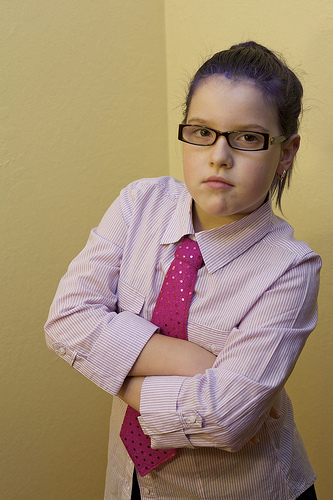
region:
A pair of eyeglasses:
[173, 118, 289, 157]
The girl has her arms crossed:
[37, 35, 323, 460]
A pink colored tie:
[117, 236, 207, 479]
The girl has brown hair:
[173, 36, 305, 221]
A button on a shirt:
[139, 481, 153, 498]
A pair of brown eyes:
[189, 123, 259, 148]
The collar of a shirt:
[156, 186, 277, 278]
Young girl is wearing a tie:
[42, 38, 325, 481]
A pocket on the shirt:
[112, 277, 149, 318]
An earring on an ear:
[275, 163, 290, 184]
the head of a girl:
[148, 62, 313, 269]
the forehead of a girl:
[194, 66, 291, 137]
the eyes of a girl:
[171, 120, 291, 158]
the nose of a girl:
[183, 135, 257, 184]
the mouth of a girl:
[190, 164, 262, 200]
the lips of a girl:
[170, 171, 253, 235]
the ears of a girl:
[260, 128, 313, 191]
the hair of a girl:
[168, 41, 305, 138]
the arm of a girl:
[119, 213, 318, 469]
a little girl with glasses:
[41, 39, 323, 496]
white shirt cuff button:
[186, 414, 195, 424]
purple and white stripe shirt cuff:
[137, 373, 194, 451]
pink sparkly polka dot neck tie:
[119, 232, 202, 477]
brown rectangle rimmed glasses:
[176, 116, 292, 152]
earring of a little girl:
[279, 167, 287, 182]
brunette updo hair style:
[178, 39, 303, 213]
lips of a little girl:
[199, 174, 235, 191]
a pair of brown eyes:
[189, 126, 262, 144]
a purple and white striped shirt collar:
[158, 185, 274, 276]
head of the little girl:
[181, 67, 306, 228]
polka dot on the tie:
[180, 298, 186, 304]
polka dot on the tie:
[138, 448, 147, 457]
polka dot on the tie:
[143, 465, 147, 473]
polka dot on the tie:
[155, 454, 164, 463]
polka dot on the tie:
[128, 439, 134, 445]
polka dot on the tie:
[160, 449, 173, 456]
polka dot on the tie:
[124, 417, 134, 429]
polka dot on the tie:
[175, 308, 182, 318]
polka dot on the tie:
[180, 295, 187, 309]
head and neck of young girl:
[171, 33, 307, 244]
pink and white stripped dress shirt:
[37, 170, 327, 497]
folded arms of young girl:
[39, 187, 323, 456]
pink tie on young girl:
[118, 233, 209, 480]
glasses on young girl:
[172, 114, 300, 155]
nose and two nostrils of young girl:
[203, 131, 236, 170]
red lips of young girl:
[197, 169, 239, 194]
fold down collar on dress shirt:
[155, 179, 285, 277]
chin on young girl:
[191, 189, 247, 218]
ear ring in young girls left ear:
[272, 164, 293, 190]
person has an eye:
[193, 128, 211, 137]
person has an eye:
[238, 133, 257, 141]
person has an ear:
[280, 135, 299, 176]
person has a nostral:
[219, 162, 227, 169]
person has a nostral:
[210, 161, 214, 165]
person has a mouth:
[198, 175, 236, 188]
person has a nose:
[209, 136, 232, 167]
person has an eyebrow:
[235, 122, 267, 131]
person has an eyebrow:
[189, 116, 215, 127]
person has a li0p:
[205, 174, 236, 184]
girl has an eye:
[189, 127, 213, 136]